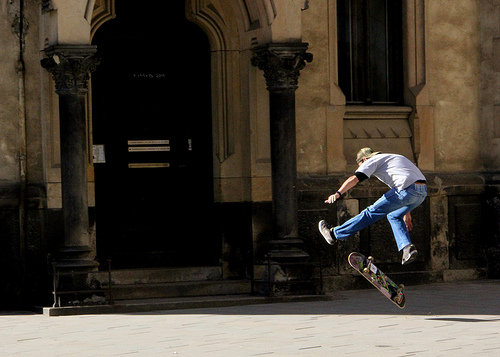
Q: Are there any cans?
A: No, there are no cans.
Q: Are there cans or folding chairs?
A: No, there are no cans or folding chairs.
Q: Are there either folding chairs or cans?
A: No, there are no cans or folding chairs.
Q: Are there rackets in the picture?
A: No, there are no rackets.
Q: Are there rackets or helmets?
A: No, there are no rackets or helmets.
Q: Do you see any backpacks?
A: Yes, there is a backpack.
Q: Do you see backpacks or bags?
A: Yes, there is a backpack.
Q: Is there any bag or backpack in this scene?
A: Yes, there is a backpack.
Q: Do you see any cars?
A: No, there are no cars.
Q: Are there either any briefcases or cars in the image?
A: No, there are no cars or briefcases.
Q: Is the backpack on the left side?
A: No, the backpack is on the right of the image.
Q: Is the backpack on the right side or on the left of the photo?
A: The backpack is on the right of the image.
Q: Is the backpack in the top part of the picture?
A: No, the backpack is in the bottom of the image.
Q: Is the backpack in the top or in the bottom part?
A: The backpack is in the bottom of the image.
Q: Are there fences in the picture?
A: No, there are no fences.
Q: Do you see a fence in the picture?
A: No, there are no fences.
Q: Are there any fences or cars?
A: No, there are no fences or cars.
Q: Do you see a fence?
A: No, there are no fences.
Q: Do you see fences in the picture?
A: No, there are no fences.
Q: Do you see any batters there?
A: No, there are no batters.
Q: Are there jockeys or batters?
A: No, there are no batters or jockeys.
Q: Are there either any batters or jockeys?
A: No, there are no batters or jockeys.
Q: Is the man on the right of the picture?
A: Yes, the man is on the right of the image.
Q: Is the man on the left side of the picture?
A: No, the man is on the right of the image.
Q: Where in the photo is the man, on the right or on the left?
A: The man is on the right of the image.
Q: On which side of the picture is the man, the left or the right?
A: The man is on the right of the image.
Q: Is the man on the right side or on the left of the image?
A: The man is on the right of the image.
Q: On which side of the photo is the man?
A: The man is on the right of the image.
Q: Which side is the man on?
A: The man is on the right of the image.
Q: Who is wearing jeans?
A: The man is wearing jeans.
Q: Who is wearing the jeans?
A: The man is wearing jeans.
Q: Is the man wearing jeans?
A: Yes, the man is wearing jeans.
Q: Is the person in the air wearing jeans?
A: Yes, the man is wearing jeans.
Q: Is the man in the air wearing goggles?
A: No, the man is wearing jeans.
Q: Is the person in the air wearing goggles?
A: No, the man is wearing jeans.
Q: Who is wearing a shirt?
A: The man is wearing a shirt.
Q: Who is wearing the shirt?
A: The man is wearing a shirt.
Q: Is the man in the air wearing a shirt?
A: Yes, the man is wearing a shirt.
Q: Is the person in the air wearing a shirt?
A: Yes, the man is wearing a shirt.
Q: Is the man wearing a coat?
A: No, the man is wearing a shirt.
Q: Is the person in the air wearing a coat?
A: No, the man is wearing a shirt.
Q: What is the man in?
A: The man is in the air.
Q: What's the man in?
A: The man is in the air.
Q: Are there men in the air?
A: Yes, there is a man in the air.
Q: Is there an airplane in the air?
A: No, there is a man in the air.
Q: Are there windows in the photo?
A: Yes, there is a window.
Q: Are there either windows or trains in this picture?
A: Yes, there is a window.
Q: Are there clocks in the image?
A: No, there are no clocks.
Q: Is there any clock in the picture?
A: No, there are no clocks.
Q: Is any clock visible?
A: No, there are no clocks.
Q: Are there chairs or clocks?
A: No, there are no clocks or chairs.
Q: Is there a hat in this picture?
A: Yes, there is a hat.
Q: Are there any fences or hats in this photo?
A: Yes, there is a hat.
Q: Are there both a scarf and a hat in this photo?
A: No, there is a hat but no scarves.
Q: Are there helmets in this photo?
A: No, there are no helmets.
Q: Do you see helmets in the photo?
A: No, there are no helmets.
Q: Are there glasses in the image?
A: No, there are no glasses.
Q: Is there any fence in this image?
A: No, there are no fences.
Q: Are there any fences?
A: No, there are no fences.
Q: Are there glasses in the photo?
A: No, there are no glasses.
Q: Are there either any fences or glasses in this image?
A: No, there are no glasses or fences.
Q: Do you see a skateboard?
A: Yes, there is a skateboard.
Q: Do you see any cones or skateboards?
A: Yes, there is a skateboard.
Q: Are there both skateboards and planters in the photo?
A: No, there is a skateboard but no planters.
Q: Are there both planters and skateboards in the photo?
A: No, there is a skateboard but no planters.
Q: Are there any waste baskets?
A: No, there are no waste baskets.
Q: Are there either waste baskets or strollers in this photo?
A: No, there are no waste baskets or strollers.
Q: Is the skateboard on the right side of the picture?
A: Yes, the skateboard is on the right of the image.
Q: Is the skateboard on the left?
A: No, the skateboard is on the right of the image.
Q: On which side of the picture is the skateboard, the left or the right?
A: The skateboard is on the right of the image.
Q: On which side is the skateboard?
A: The skateboard is on the right of the image.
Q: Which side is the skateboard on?
A: The skateboard is on the right of the image.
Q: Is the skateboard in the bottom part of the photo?
A: Yes, the skateboard is in the bottom of the image.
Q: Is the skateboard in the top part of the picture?
A: No, the skateboard is in the bottom of the image.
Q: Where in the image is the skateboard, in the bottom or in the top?
A: The skateboard is in the bottom of the image.